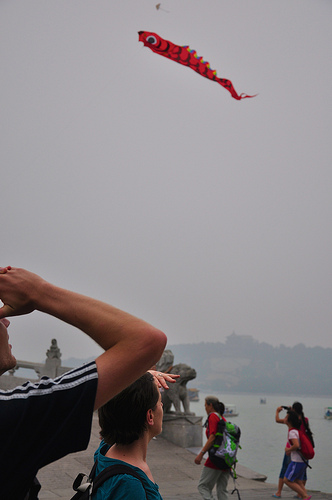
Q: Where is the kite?
A: In the sky.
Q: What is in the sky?
A: Kite.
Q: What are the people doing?
A: Watching the kite.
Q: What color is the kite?
A: Black and red.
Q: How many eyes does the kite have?
A: 1.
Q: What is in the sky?
A: A kite.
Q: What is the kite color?
A: Red.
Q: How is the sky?
A: Overcast.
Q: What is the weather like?
A: Foggy.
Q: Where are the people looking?
A: At the kite.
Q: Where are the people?
A: By the water.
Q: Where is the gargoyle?
A: Along the waterside.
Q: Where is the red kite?
A: In the sky.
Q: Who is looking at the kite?
A: A man and woman.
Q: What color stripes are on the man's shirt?
A: White.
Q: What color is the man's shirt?
A: Black.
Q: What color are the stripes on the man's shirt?
A: White.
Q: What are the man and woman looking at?
A: Sky.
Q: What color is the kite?
A: Red.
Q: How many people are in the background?
A: 4.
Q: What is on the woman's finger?
A: A ring.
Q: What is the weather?
A: Rainy.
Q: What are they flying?
A: Kite.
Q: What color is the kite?
A: Red.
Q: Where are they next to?
A: Water.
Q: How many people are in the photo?
A: 6.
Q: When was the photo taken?
A: Daytime.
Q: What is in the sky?
A: Kite.